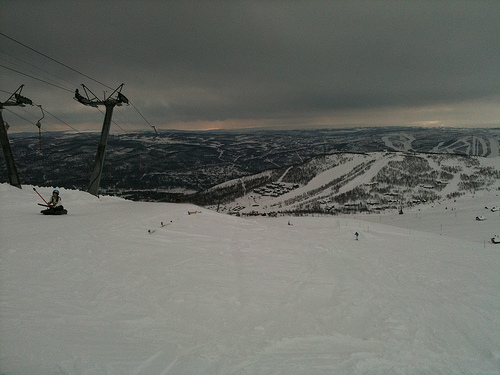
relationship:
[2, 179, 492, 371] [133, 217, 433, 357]
snow has tracks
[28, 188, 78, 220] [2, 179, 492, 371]
person sitting in snow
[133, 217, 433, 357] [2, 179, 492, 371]
tracks are on snow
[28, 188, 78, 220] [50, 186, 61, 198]
person wearing helmet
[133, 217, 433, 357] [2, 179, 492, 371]
tracks are in snow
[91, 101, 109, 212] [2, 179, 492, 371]
pole covered in snow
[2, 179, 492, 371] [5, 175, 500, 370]
snow on top of mountain